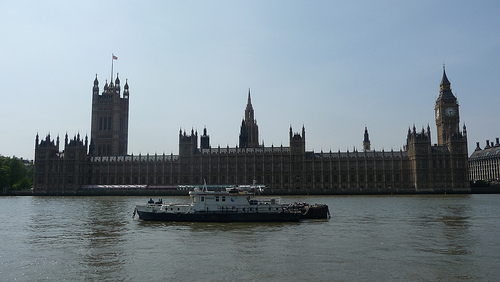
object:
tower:
[90, 50, 132, 152]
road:
[18, 190, 473, 198]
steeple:
[239, 84, 264, 147]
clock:
[445, 105, 457, 118]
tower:
[433, 57, 475, 181]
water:
[371, 201, 500, 280]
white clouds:
[206, 102, 239, 117]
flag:
[113, 55, 119, 60]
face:
[444, 108, 458, 115]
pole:
[111, 51, 115, 84]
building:
[33, 51, 500, 192]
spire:
[246, 87, 251, 103]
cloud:
[191, 92, 217, 103]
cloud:
[2, 127, 26, 149]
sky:
[1, 0, 498, 160]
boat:
[132, 178, 333, 222]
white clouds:
[80, 54, 111, 73]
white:
[207, 199, 214, 207]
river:
[1, 218, 500, 282]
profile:
[137, 177, 333, 223]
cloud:
[470, 111, 495, 129]